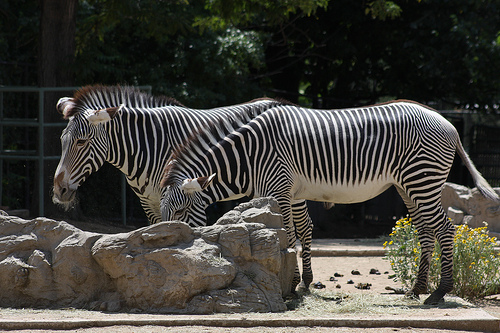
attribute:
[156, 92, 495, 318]
zebra — black, white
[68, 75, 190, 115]
main — short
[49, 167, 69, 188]
nose — brown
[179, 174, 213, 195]
ear — black, white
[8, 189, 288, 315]
outcropping — rocky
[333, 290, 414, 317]
patch — small, grass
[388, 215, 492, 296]
flowers — yellow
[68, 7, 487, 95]
trees — green